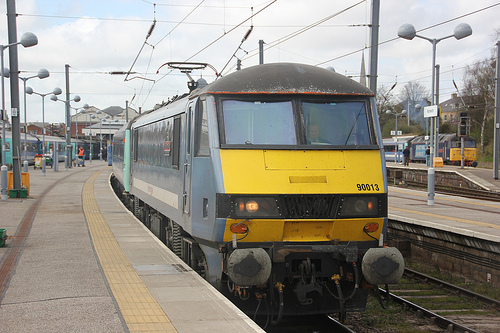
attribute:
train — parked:
[122, 61, 407, 331]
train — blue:
[1, 135, 112, 162]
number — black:
[357, 184, 379, 192]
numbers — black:
[334, 172, 390, 195]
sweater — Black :
[75, 144, 86, 159]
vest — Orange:
[75, 145, 86, 159]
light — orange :
[236, 201, 247, 213]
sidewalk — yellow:
[0, 139, 265, 331]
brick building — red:
[437, 94, 492, 128]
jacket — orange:
[76, 148, 86, 154]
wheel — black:
[164, 222, 183, 257]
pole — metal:
[5, 0, 21, 187]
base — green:
[8, 186, 28, 198]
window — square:
[217, 98, 298, 145]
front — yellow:
[205, 140, 393, 247]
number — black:
[355, 180, 381, 194]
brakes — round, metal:
[222, 240, 406, 291]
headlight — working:
[227, 194, 278, 217]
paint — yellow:
[217, 149, 386, 244]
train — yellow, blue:
[105, 58, 401, 324]